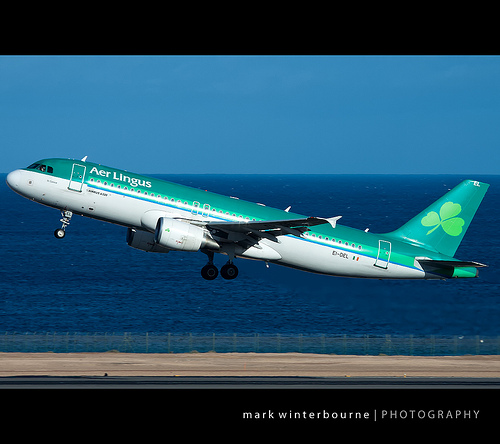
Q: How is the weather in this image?
A: It is clear.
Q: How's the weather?
A: It is clear.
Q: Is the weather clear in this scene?
A: Yes, it is clear.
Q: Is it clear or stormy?
A: It is clear.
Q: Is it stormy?
A: No, it is clear.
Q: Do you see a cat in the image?
A: No, there are no cats.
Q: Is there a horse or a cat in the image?
A: No, there are no cats or horses.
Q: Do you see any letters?
A: Yes, there are letters.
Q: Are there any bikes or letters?
A: Yes, there are letters.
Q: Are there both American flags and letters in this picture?
A: No, there are letters but no American flags.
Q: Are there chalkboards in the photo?
A: No, there are no chalkboards.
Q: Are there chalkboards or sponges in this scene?
A: No, there are no chalkboards or sponges.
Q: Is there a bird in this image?
A: No, there are no birds.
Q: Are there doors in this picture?
A: Yes, there is a door.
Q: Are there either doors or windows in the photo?
A: Yes, there is a door.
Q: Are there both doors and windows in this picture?
A: Yes, there are both a door and a window.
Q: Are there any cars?
A: No, there are no cars.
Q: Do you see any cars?
A: No, there are no cars.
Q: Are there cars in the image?
A: No, there are no cars.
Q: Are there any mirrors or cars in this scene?
A: No, there are no cars or mirrors.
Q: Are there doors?
A: Yes, there is a door.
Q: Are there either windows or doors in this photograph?
A: Yes, there is a door.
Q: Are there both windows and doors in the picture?
A: Yes, there are both a door and windows.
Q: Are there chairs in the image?
A: No, there are no chairs.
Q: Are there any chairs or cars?
A: No, there are no chairs or cars.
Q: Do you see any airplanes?
A: Yes, there is an airplane.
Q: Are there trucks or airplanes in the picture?
A: Yes, there is an airplane.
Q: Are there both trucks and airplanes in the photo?
A: No, there is an airplane but no trucks.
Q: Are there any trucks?
A: No, there are no trucks.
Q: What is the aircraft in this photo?
A: The aircraft is an airplane.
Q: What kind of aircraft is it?
A: The aircraft is an airplane.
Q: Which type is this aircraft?
A: This is an airplane.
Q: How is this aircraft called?
A: This is an airplane.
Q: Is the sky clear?
A: Yes, the sky is clear.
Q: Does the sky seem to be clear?
A: Yes, the sky is clear.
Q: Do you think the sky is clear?
A: Yes, the sky is clear.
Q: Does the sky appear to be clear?
A: Yes, the sky is clear.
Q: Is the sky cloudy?
A: No, the sky is clear.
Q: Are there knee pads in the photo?
A: No, there are no knee pads.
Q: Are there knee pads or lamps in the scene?
A: No, there are no knee pads or lamps.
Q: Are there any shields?
A: No, there are no shields.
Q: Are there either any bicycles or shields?
A: No, there are no shields or bicycles.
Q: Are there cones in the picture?
A: No, there are no cones.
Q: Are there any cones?
A: No, there are no cones.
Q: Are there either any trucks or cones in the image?
A: No, there are no cones or trucks.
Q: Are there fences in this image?
A: Yes, there is a fence.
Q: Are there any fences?
A: Yes, there is a fence.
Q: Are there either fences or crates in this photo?
A: Yes, there is a fence.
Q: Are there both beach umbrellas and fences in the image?
A: No, there is a fence but no beach umbrellas.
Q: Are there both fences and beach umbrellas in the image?
A: No, there is a fence but no beach umbrellas.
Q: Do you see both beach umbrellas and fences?
A: No, there is a fence but no beach umbrellas.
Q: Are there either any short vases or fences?
A: Yes, there is a short fence.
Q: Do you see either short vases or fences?
A: Yes, there is a short fence.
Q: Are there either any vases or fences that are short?
A: Yes, the fence is short.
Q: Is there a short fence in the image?
A: Yes, there is a short fence.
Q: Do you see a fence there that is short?
A: Yes, there is a fence that is short.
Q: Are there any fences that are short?
A: Yes, there is a fence that is short.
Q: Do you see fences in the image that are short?
A: Yes, there is a fence that is short.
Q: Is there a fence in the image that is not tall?
A: Yes, there is a short fence.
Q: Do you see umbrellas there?
A: No, there are no umbrellas.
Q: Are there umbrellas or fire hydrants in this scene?
A: No, there are no umbrellas or fire hydrants.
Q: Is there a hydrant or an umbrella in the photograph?
A: No, there are no umbrellas or fire hydrants.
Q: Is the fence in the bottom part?
A: Yes, the fence is in the bottom of the image.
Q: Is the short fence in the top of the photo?
A: No, the fence is in the bottom of the image.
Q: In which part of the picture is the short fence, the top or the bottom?
A: The fence is in the bottom of the image.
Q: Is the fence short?
A: Yes, the fence is short.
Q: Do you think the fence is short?
A: Yes, the fence is short.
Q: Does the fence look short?
A: Yes, the fence is short.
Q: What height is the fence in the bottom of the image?
A: The fence is short.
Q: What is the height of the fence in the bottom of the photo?
A: The fence is short.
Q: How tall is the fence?
A: The fence is short.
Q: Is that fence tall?
A: No, the fence is short.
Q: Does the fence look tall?
A: No, the fence is short.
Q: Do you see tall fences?
A: No, there is a fence but it is short.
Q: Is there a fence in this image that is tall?
A: No, there is a fence but it is short.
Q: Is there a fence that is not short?
A: No, there is a fence but it is short.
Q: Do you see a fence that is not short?
A: No, there is a fence but it is short.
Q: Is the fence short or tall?
A: The fence is short.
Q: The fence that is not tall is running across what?
A: The fence is running across the runway.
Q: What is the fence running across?
A: The fence is running across the runway.